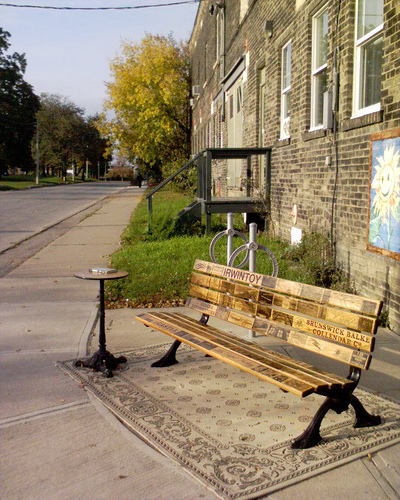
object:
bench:
[131, 259, 385, 451]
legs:
[287, 393, 381, 450]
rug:
[53, 337, 400, 499]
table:
[71, 269, 132, 379]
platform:
[196, 193, 268, 237]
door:
[256, 80, 266, 189]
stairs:
[171, 198, 203, 236]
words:
[304, 319, 371, 349]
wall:
[184, 1, 399, 342]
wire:
[2, 1, 200, 13]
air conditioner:
[192, 84, 201, 96]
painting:
[363, 125, 399, 261]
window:
[274, 31, 301, 141]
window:
[300, 0, 336, 132]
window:
[347, 0, 392, 119]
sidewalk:
[4, 187, 145, 500]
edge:
[298, 378, 359, 399]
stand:
[97, 281, 108, 352]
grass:
[106, 232, 183, 298]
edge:
[192, 478, 225, 499]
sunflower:
[371, 146, 400, 246]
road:
[0, 177, 137, 264]